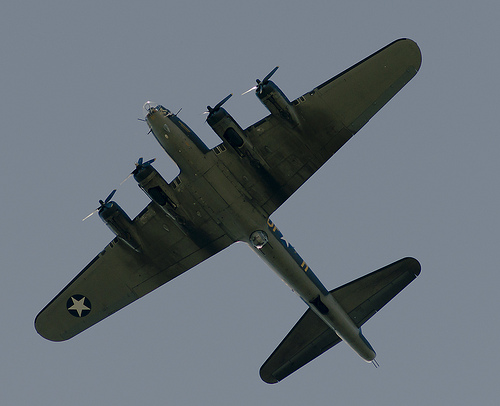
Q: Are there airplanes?
A: Yes, there is an airplane.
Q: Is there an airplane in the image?
A: Yes, there is an airplane.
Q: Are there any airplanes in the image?
A: Yes, there is an airplane.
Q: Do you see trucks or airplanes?
A: Yes, there is an airplane.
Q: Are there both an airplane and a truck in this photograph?
A: No, there is an airplane but no trucks.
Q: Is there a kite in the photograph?
A: No, there are no kites.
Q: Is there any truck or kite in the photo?
A: No, there are no kites or trucks.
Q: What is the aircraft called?
A: The aircraft is an airplane.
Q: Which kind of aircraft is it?
A: The aircraft is an airplane.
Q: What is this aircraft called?
A: This is an airplane.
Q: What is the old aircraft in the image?
A: The aircraft is an airplane.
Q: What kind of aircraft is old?
A: The aircraft is an airplane.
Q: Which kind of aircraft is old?
A: The aircraft is an airplane.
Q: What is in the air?
A: The plane is in the air.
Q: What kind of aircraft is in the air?
A: The aircraft is an airplane.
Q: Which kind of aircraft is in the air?
A: The aircraft is an airplane.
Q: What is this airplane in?
A: The airplane is in the air.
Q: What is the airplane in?
A: The airplane is in the air.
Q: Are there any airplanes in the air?
A: Yes, there is an airplane in the air.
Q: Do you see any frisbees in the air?
A: No, there is an airplane in the air.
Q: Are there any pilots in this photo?
A: No, there are no pilots.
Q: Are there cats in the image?
A: No, there are no cats.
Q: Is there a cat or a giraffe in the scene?
A: No, there are no cats or giraffes.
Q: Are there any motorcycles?
A: No, there are no motorcycles.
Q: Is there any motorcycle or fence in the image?
A: No, there are no motorcycles or fences.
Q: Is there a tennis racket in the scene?
A: No, there are no rackets.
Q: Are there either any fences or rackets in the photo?
A: No, there are no rackets or fences.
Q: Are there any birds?
A: No, there are no birds.